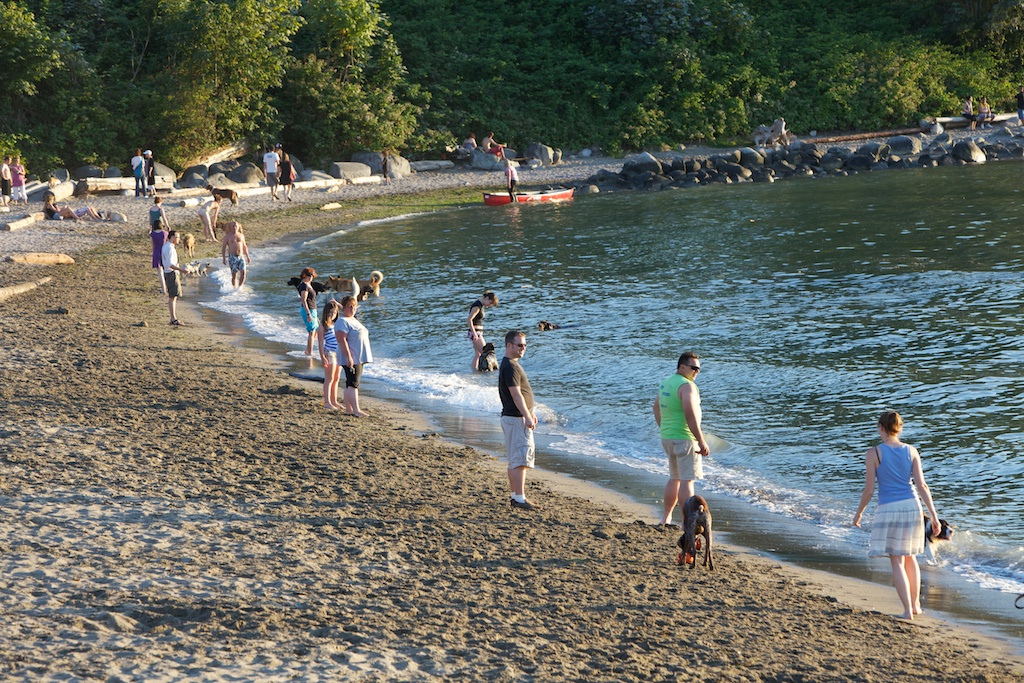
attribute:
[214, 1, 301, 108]
leaves — green, small, sunlit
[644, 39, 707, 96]
leaves — green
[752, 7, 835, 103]
leaves — green